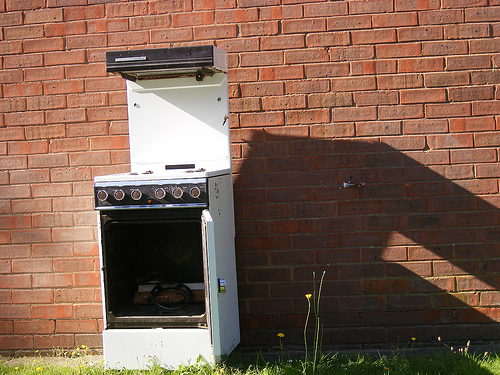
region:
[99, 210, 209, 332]
The oven door has been removed.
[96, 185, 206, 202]
Six dials are on the oven.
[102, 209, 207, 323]
The inside of the oven is dark.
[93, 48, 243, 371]
The kitchen appliance is white.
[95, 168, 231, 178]
A stove is on the oven.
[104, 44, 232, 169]
The oven has a stand for a microwave.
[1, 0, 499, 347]
The wall is made of red brick.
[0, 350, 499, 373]
Grass is on the ground.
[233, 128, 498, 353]
The kitchen appliance is casting a shadow.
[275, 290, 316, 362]
The dandelions are very tall.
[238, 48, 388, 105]
red brick wall behind object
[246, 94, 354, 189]
shadow on the wall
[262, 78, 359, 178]
light and dark wall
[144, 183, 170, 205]
knob on the oven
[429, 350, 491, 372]
shadow on the grass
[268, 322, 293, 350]
yellow flower top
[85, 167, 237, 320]
broken down oven on the grass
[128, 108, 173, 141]
light hitting the object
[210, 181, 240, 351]
side of the object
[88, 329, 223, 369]
bottom of the object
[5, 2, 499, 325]
The wall is brick.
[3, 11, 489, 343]
The brick is red.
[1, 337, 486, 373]
The grass is green.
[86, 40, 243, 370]
The oven is old.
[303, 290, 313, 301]
The flower is yellow.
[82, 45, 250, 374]
The oven is white.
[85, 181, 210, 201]
The knobs are black.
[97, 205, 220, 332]
There is no door.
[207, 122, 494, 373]
The oven is casing a shadow.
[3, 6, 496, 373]
The sun is shining.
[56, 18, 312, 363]
a stove sits outside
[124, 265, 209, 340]
the cord is inside the oven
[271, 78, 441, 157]
the building is brick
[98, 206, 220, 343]
the oven door is missing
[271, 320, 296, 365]
a dandelion is growning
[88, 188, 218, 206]
the burner knobs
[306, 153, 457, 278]
the bricks are red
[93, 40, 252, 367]
the stove is white & black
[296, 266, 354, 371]
this weed has a flower & is tall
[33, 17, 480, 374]
the stove looks odd sitting alone outside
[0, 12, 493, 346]
The wall is red.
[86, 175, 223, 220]
The knobs are black.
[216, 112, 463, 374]
The oven is casting a shadow.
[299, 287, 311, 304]
The flower is yellow.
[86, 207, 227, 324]
The door is off.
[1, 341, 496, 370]
The grass is small.